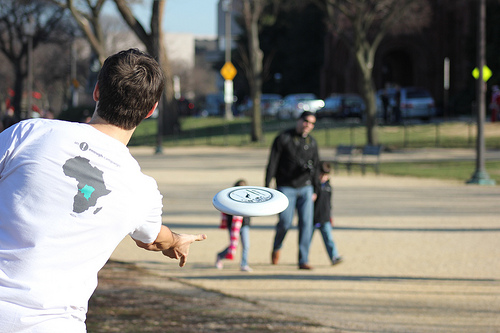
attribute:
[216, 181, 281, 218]
frisbee — white, round, plastic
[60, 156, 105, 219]
africa — black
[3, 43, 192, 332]
man — standing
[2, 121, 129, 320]
shirt — white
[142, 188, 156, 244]
sleeve — short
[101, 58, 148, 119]
hair — dark, black, short, combed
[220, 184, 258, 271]
girl — walking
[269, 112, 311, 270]
man — walking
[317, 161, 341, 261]
boy — walking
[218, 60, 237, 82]
sign — yellow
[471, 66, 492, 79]
sign — yellow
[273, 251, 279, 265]
shoe — brown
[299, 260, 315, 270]
shoe — brown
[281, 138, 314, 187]
jacket — black, closed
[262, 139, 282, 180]
sleeve — long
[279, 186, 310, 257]
pants — blue